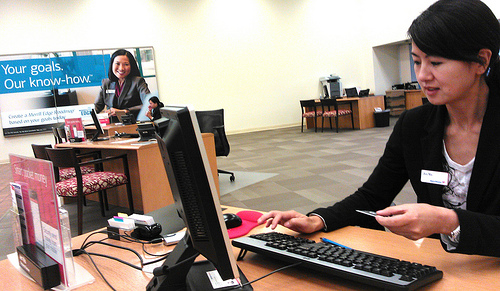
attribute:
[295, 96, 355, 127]
chairs — empty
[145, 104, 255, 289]
monitor — flat, screen, computer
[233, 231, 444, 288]
keyboard — black, computer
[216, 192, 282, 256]
mousepad — red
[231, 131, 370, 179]
floor — tan, carpeted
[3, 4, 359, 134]
wall — white, large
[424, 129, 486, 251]
top — black, white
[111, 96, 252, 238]
monitor — computer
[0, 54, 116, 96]
sign — large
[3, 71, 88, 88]
lettering — blue, white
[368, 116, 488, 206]
jacket — black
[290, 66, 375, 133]
desk — empty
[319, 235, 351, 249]
pen — blue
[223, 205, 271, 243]
mousepad — red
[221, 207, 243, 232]
mouse — black, computer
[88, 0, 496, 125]
women — young, Asian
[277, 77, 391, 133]
desk — empty